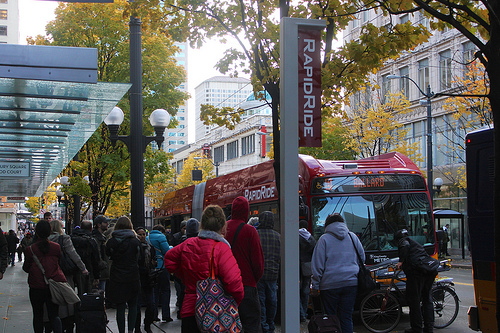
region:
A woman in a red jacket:
[181, 198, 258, 325]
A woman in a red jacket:
[138, 163, 253, 323]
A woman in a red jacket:
[216, 255, 248, 317]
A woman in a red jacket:
[221, 221, 297, 331]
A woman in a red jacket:
[160, 201, 223, 318]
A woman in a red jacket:
[193, 211, 233, 324]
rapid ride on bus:
[237, 184, 288, 208]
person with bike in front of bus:
[362, 227, 469, 331]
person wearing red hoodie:
[215, 194, 265, 283]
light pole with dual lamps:
[105, 15, 182, 252]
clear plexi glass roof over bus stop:
[6, 87, 134, 179]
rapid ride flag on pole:
[288, 18, 337, 156]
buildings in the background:
[187, 0, 493, 158]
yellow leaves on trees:
[114, 150, 217, 215]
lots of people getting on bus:
[26, 212, 294, 326]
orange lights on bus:
[317, 164, 437, 191]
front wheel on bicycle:
[358, 289, 403, 326]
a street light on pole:
[145, 112, 174, 146]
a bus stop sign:
[302, 32, 322, 140]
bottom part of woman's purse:
[45, 279, 80, 302]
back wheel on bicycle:
[436, 284, 458, 324]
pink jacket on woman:
[188, 244, 227, 271]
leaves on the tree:
[143, 43, 172, 84]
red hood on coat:
[226, 187, 249, 222]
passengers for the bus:
[103, 217, 164, 290]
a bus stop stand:
[438, 210, 465, 248]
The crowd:
[34, 235, 235, 327]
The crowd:
[61, 145, 318, 313]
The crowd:
[230, 302, 245, 314]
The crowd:
[150, 228, 338, 323]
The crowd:
[110, 201, 252, 286]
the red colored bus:
[303, 146, 468, 311]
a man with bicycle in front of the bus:
[359, 223, 441, 332]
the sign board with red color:
[275, 11, 334, 297]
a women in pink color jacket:
[167, 196, 259, 324]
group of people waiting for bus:
[144, 203, 299, 311]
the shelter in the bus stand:
[12, 31, 117, 206]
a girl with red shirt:
[20, 206, 83, 324]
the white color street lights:
[97, 85, 189, 167]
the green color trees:
[70, 13, 124, 65]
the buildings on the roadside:
[195, 66, 266, 164]